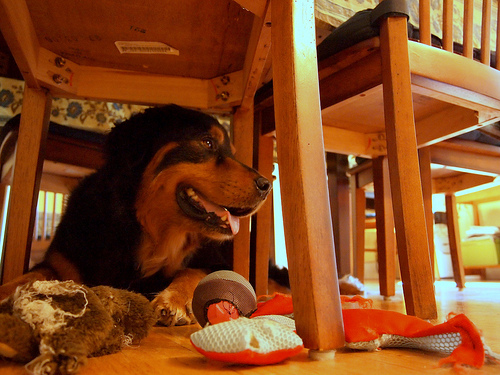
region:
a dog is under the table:
[57, 89, 251, 366]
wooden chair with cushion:
[312, 0, 497, 302]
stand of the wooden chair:
[380, 45, 435, 337]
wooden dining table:
[8, 4, 271, 118]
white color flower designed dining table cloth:
[63, 103, 119, 130]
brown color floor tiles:
[123, 349, 184, 372]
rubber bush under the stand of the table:
[303, 346, 344, 363]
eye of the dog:
[189, 133, 221, 160]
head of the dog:
[118, 105, 270, 250]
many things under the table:
[16, 267, 406, 374]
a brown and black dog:
[38, 93, 273, 325]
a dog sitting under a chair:
[1, 0, 346, 357]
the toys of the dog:
[191, 269, 498, 372]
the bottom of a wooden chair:
[323, 3, 498, 318]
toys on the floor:
[0, 273, 491, 373]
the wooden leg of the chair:
[383, 15, 443, 320]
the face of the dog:
[127, 102, 272, 239]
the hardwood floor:
[129, 345, 194, 371]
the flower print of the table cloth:
[50, 100, 127, 127]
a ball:
[188, 270, 259, 327]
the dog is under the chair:
[4, 4, 344, 321]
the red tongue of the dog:
[224, 211, 241, 234]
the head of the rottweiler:
[91, 106, 270, 256]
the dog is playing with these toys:
[5, 281, 484, 373]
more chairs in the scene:
[329, 0, 491, 342]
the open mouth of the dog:
[177, 175, 253, 235]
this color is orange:
[353, 311, 403, 333]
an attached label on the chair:
[114, 39, 177, 54]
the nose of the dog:
[253, 173, 270, 198]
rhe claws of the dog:
[156, 299, 191, 326]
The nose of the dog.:
[258, 175, 267, 192]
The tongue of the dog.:
[205, 202, 241, 232]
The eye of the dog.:
[200, 138, 212, 148]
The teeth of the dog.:
[186, 189, 230, 226]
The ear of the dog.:
[108, 114, 148, 169]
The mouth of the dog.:
[179, 179, 256, 240]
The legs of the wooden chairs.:
[3, 30, 442, 353]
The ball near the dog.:
[193, 267, 250, 318]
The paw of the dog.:
[154, 282, 197, 327]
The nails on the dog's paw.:
[155, 305, 177, 317]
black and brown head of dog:
[102, 110, 257, 232]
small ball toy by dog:
[189, 268, 251, 320]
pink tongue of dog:
[222, 210, 242, 231]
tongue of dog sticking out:
[212, 196, 246, 239]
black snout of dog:
[255, 176, 279, 193]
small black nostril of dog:
[258, 180, 268, 189]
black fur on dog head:
[97, 108, 206, 180]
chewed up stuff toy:
[15, 283, 151, 361]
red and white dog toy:
[198, 317, 295, 359]